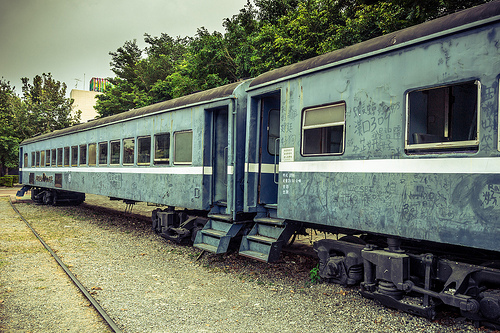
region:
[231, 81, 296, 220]
an open door way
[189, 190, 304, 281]
a few blue stairs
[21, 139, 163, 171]
a row of windows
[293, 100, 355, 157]
half drawn window shutters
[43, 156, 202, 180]
a broad white stripe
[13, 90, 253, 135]
a black metal roof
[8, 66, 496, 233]
a few blue trains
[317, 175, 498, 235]
graffiti of train side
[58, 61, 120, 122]
a large building in background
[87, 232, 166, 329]
a large amount of gravel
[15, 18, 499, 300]
Old train cars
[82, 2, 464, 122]
Green trees along the tracks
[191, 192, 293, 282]
Steps leading into the train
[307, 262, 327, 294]
Weeds growing under the train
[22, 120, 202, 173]
Windows on the side of the train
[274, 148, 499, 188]
White stripe painted on the side of the train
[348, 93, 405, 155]
Graffiti on the train car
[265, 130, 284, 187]
Handle at the doorway of the train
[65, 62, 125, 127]
Tall buildings in the background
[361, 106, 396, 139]
Number 304 written on the train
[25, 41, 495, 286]
two passenger train cars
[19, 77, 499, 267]
blue cars with white stripe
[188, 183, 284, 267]
steps onto the train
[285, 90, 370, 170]
open window on train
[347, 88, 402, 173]
graffiti on train car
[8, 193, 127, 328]
rail for railroad track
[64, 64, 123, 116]
buildings behind train cars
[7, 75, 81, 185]
tree behind train car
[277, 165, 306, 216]
stenciled letters and numbers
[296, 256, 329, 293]
weed growing beside train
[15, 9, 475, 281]
There is a blue train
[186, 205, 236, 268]
There are steps onto the train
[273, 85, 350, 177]
There are windows on the train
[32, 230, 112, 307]
There are train tracks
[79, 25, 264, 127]
Green trees behind the train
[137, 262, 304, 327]
Gravel underneath the train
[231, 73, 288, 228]
A door to the train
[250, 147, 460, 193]
The train has a white stripe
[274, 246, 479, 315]
The train's wheels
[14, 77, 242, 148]
train has a black roof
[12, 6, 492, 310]
an old blue train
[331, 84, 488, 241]
a lot of writing on the side of a train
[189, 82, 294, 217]
two open doorways to two train cars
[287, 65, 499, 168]
two open windows on a train car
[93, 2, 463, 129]
many tree tops peeking over the top of a train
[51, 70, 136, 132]
two building behind the trees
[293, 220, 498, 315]
machinery on the train's undercarriage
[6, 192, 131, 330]
a metal rail buried in the ground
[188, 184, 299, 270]
steps leading into the train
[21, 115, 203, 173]
many many windows on an old train car